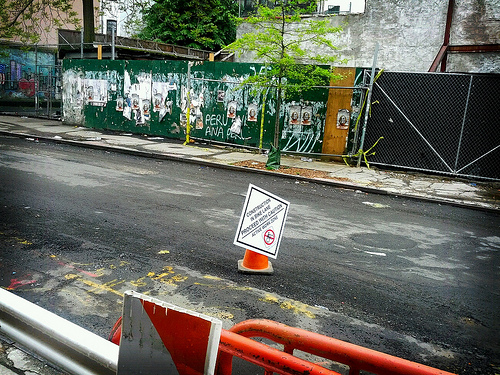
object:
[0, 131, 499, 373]
road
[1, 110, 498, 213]
sidewalk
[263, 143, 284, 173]
mulch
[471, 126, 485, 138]
ground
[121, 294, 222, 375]
sign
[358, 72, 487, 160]
concession stand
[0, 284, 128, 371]
gaurd rail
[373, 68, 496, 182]
fence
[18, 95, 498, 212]
side walk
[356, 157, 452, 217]
sidewalk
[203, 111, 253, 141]
tagging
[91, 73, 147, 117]
wall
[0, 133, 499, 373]
cement road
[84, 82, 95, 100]
poster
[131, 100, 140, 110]
poster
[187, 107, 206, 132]
poster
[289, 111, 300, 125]
poster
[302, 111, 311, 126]
poster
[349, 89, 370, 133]
tape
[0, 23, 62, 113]
graffiti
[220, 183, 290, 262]
sign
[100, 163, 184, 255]
street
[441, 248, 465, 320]
water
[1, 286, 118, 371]
railing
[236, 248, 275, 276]
cone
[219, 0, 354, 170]
brtree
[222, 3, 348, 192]
tree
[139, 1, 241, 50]
tree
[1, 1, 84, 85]
tree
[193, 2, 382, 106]
leaves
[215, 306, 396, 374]
rails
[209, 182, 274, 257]
sign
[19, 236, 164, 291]
marking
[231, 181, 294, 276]
traffic cone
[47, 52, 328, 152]
green boards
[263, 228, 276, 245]
posting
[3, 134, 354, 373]
road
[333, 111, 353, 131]
posters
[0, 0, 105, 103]
building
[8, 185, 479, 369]
project